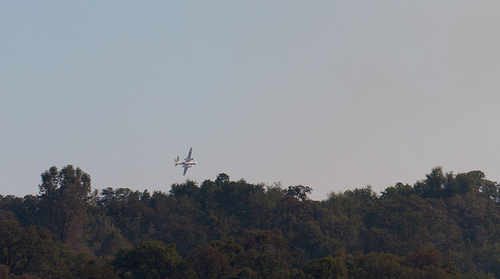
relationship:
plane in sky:
[173, 145, 198, 176] [1, 2, 493, 192]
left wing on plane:
[184, 147, 192, 162] [169, 143, 199, 178]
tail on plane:
[173, 157, 179, 167] [174, 146, 197, 175]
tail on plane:
[173, 157, 179, 167] [175, 147, 195, 174]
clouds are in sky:
[190, 17, 498, 167] [115, 74, 477, 183]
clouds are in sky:
[248, 71, 293, 126] [94, 106, 429, 198]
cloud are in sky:
[146, 79, 233, 107] [13, 15, 471, 222]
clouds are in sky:
[328, 21, 455, 96] [86, 82, 414, 177]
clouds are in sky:
[237, 82, 448, 158] [1, 2, 493, 192]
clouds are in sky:
[328, 21, 455, 96] [141, 121, 385, 196]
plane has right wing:
[173, 145, 198, 176] [181, 165, 187, 176]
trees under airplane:
[5, 160, 497, 277] [164, 141, 205, 178]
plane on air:
[173, 145, 198, 176] [138, 121, 228, 179]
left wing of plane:
[184, 147, 192, 162] [173, 145, 198, 176]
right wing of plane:
[181, 165, 187, 176] [173, 145, 195, 175]